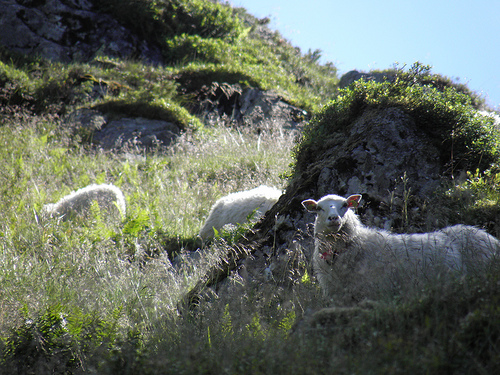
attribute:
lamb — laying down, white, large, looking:
[296, 194, 499, 316]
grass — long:
[4, 129, 268, 333]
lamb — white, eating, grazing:
[39, 178, 126, 238]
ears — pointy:
[301, 194, 367, 213]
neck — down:
[196, 208, 218, 250]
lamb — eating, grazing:
[185, 183, 281, 255]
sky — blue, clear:
[237, 1, 498, 111]